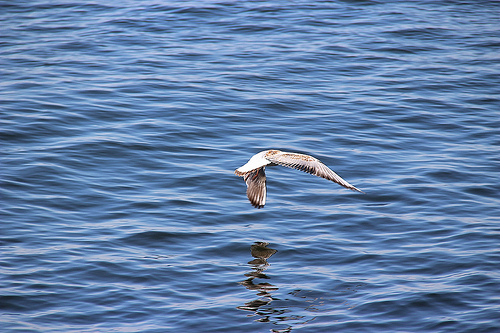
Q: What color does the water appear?
A: Blue.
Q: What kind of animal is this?
A: A bird.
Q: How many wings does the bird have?
A: Two.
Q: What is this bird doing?
A: Flying.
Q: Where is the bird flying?
A: Over the water.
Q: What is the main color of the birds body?
A: White.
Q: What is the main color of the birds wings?
A: Brown.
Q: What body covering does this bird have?
A: Feathers.